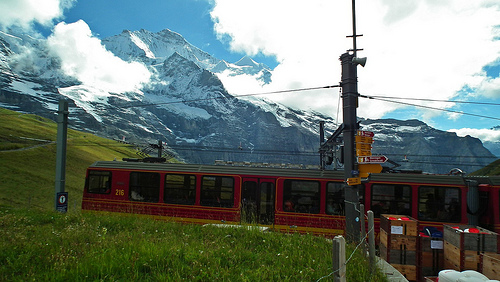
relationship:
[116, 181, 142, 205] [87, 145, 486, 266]
216 on train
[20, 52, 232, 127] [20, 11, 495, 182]
snow on mountains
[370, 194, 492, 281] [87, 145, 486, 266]
boxes by train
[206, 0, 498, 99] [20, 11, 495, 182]
cloud by mountains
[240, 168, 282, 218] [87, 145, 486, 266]
door on train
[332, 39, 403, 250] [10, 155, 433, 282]
pole in ground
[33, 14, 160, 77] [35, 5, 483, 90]
clouds in sky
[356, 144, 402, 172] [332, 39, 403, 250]
sign on pole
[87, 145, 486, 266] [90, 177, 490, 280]
train on tracks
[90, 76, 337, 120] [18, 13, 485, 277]
wires next to train tracks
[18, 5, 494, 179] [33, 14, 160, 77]
sky has clouds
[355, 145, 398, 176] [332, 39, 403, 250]
sign has pole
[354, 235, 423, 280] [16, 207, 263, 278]
curb next to grass